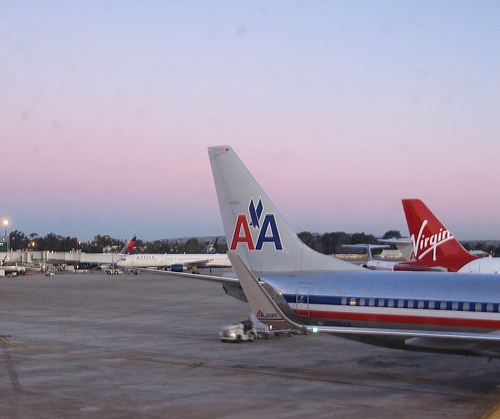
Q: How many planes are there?
A: Four.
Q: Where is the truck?
A: Behind the planes.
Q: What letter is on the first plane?
A: A.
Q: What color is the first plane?
A: Silver.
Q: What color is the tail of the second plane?
A: Red.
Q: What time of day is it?
A: Sunset.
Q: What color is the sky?
A: Mauve and blue.